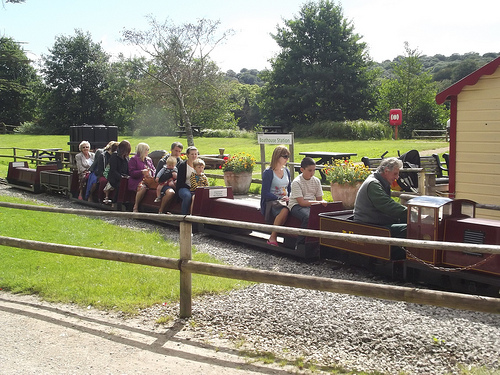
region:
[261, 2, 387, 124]
large green tree along side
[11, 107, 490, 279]
small passenger train on track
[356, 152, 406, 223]
passenger in small train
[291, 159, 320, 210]
passenger in small train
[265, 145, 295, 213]
passenger in small train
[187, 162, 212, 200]
passenger in small train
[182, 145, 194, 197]
passenger in small train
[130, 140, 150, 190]
passenger in small train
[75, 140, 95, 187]
passenger in small train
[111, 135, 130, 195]
passenger in small train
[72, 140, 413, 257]
the people on the train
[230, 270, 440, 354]
the rocks next to the train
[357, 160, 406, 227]
the old man in the train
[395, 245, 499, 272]
the chain on the train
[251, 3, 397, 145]
the biggest tree in the back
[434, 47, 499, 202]
the yellow and red building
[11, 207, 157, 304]
the green lush grass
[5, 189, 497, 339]
the wooden fence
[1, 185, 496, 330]
the fence made of wood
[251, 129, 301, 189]
the sign near the train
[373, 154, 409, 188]
the head of a man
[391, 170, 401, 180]
the nose of a man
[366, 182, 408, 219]
the arm of a man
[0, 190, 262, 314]
a patch of green grass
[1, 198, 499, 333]
a brown wooden fence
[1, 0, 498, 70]
a blue and white sky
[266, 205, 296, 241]
the leg of a woman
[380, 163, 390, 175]
the ear of a man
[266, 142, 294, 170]
the head of a woman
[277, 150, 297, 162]
a pair of sunglasses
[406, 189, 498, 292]
a miniature train engine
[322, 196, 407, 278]
a miniature train car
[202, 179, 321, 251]
a miniature train car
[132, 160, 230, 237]
a miniature train car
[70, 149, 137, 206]
a miniature train car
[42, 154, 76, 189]
a miniature train car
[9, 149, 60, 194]
a miniature train car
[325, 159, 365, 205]
a large concrete flower planter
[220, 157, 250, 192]
a large concrete flower planter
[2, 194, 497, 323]
a long wooden fence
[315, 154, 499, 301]
engineer of a Tiny Town miniature train ride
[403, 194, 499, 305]
miniature train engine on a little track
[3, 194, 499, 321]
wooden rail fence bordering the train tracks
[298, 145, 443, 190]
picnic area to eat in after riding the train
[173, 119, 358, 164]
several picnic tables near the train tracks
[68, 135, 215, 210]
guests riding the miniature train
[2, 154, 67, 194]
the "caboose" of the miniature train is another bench for guests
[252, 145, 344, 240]
guests riding the miniature train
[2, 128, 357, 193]
grassy area bordering the train tracks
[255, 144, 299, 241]
woman wearing a blue sweater